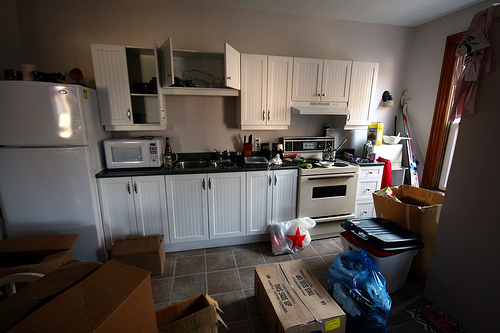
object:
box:
[253, 259, 349, 332]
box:
[112, 225, 166, 277]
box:
[155, 293, 228, 332]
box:
[0, 257, 158, 332]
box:
[1, 233, 79, 276]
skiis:
[400, 84, 422, 189]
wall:
[0, 0, 413, 154]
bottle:
[162, 135, 175, 171]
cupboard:
[292, 54, 350, 103]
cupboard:
[158, 37, 240, 94]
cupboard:
[239, 52, 291, 131]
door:
[241, 53, 268, 127]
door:
[222, 42, 240, 91]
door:
[159, 34, 174, 88]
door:
[89, 45, 132, 127]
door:
[149, 37, 167, 127]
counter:
[94, 154, 297, 178]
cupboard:
[88, 37, 164, 130]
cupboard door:
[342, 58, 382, 129]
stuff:
[20, 62, 37, 82]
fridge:
[2, 78, 107, 265]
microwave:
[102, 136, 166, 172]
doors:
[167, 172, 209, 244]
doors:
[290, 54, 324, 104]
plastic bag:
[265, 213, 318, 258]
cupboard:
[100, 174, 170, 254]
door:
[267, 54, 292, 125]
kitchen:
[0, 0, 499, 332]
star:
[286, 226, 309, 251]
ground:
[148, 236, 481, 332]